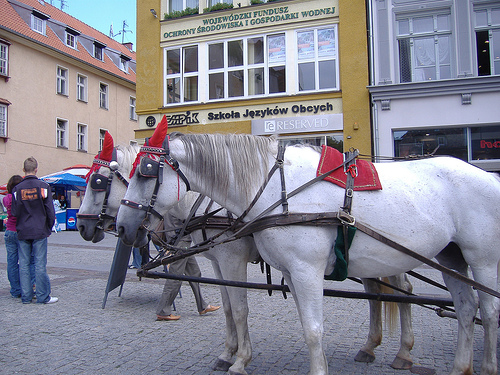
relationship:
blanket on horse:
[313, 142, 383, 192] [110, 111, 496, 366]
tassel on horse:
[126, 115, 170, 186] [110, 111, 496, 366]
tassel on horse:
[89, 128, 119, 184] [70, 129, 422, 366]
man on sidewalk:
[144, 232, 224, 323] [5, 221, 498, 365]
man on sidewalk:
[15, 155, 57, 309] [5, 221, 498, 365]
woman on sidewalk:
[1, 174, 21, 299] [5, 221, 498, 365]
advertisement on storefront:
[140, 100, 344, 130] [136, 101, 370, 171]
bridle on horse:
[120, 134, 295, 276] [110, 111, 496, 366]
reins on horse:
[291, 144, 377, 200] [110, 111, 496, 366]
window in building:
[153, 23, 341, 107] [134, 2, 370, 228]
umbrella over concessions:
[38, 164, 91, 192] [44, 200, 86, 230]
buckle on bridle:
[331, 210, 357, 229] [120, 134, 295, 276]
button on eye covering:
[146, 161, 152, 168] [137, 159, 161, 181]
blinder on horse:
[84, 176, 117, 192] [70, 129, 422, 366]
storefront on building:
[136, 101, 370, 171] [134, 2, 370, 228]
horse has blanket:
[110, 111, 496, 366] [313, 142, 383, 192]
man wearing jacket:
[15, 155, 57, 309] [8, 178, 64, 240]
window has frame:
[153, 23, 341, 107] [162, 25, 342, 110]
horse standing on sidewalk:
[110, 111, 496, 366] [5, 221, 498, 365]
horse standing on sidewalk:
[70, 129, 422, 366] [5, 221, 498, 365]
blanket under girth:
[313, 142, 383, 192] [325, 143, 361, 223]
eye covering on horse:
[137, 159, 161, 181] [110, 111, 496, 366]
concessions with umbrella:
[44, 200, 86, 230] [38, 164, 91, 192]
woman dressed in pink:
[1, 174, 21, 299] [3, 191, 22, 228]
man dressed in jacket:
[144, 232, 224, 323] [8, 178, 64, 240]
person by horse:
[157, 253, 218, 320] [70, 129, 422, 366]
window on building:
[153, 23, 341, 107] [134, 2, 370, 228]